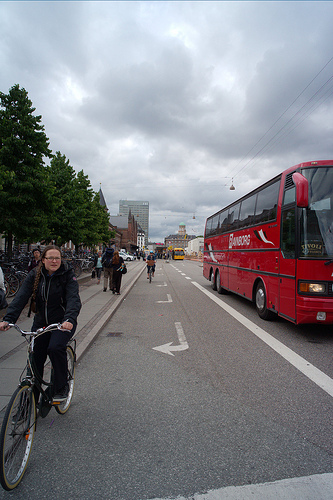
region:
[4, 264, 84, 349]
THE WOMAN IS WEARING A JACKET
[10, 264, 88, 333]
THE JACKET IS BLACK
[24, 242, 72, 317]
THE WOMAN HAS LONG HAIR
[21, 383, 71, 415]
THE WOMAN IS WEARING BLACK SHOES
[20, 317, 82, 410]
THE WOMAN IS WEARING BLACK PANTS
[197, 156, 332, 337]
THE BUS IS BRIGHT RED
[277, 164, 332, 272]
THE BUS A LARGE WINDSHIELD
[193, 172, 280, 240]
THE BUS HAS MANY WINDOWS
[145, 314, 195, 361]
THE ARROW IS PAINTED ON THE ROAD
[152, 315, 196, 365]
THE ARROW IS WHITE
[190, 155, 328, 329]
a red bus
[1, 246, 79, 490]
a woman riding a bicycle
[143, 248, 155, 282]
a person riding a bicycle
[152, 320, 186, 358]
white spray painted traffic turn sign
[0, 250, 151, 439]
a pedestrian sidewalk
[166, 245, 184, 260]
a bright yellow school bus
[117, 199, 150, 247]
a tall building in distance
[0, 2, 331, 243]
a grey cloudy sky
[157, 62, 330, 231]
overhead electric power lines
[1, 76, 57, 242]
a large green tree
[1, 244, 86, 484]
A woman on a bicycle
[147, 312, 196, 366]
A white arrow on the road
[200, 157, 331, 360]
A large red bus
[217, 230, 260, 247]
writing on the bus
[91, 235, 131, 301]
People on the sidewalk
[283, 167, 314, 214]
A rear view mirror on the bus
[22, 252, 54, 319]
Braids in the woman's hair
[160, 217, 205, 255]
A building with a turquoise dome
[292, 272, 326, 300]
A headlight on the bus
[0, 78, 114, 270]
Trees along the street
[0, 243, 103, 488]
girl on bike on side of road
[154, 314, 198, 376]
turn arrow on road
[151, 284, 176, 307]
turn arrow on road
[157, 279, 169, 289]
turn arrow on road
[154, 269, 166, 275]
turn arrow on road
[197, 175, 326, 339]
red bus on road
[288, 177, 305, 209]
side mirror on bus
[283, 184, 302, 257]
side window on bus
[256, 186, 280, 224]
side window on bus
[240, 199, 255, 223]
side window on bus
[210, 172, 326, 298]
this is a bus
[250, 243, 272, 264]
the bus is red in color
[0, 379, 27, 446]
this is a bike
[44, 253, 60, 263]
she is wearing spectacles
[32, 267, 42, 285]
the hair is long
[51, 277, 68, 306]
the jacket is black in color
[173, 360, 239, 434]
the road is tarmacked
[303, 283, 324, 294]
the light is on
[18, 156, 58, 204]
the leaves are green in color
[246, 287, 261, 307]
this is the wheel